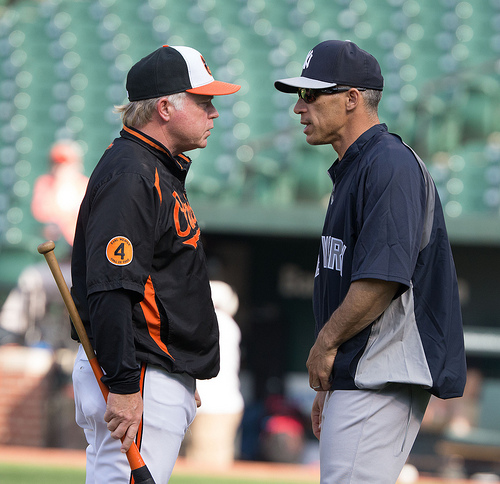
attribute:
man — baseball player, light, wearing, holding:
[45, 26, 320, 443]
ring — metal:
[300, 373, 345, 400]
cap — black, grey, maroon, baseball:
[256, 23, 401, 100]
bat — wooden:
[12, 238, 135, 401]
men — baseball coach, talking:
[56, 11, 451, 271]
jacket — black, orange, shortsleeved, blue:
[80, 137, 237, 360]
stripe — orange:
[136, 262, 165, 366]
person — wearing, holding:
[201, 19, 453, 426]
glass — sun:
[252, 70, 348, 158]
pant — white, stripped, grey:
[50, 334, 210, 483]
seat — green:
[204, 166, 303, 257]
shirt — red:
[10, 175, 101, 224]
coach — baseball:
[41, 34, 297, 390]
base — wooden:
[42, 239, 65, 259]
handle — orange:
[24, 221, 92, 329]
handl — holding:
[49, 342, 144, 451]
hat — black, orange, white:
[112, 25, 217, 130]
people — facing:
[60, 21, 452, 472]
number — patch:
[90, 233, 147, 289]